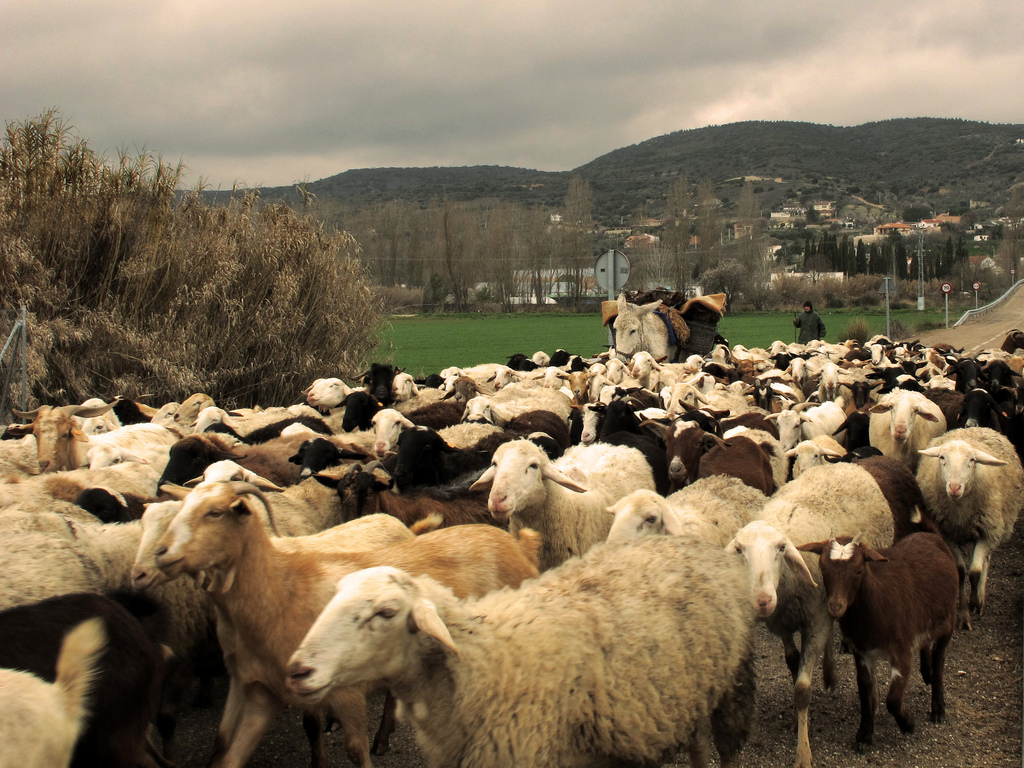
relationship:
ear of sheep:
[397, 610, 523, 712] [289, 552, 823, 758]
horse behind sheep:
[611, 284, 700, 364] [527, 335, 944, 560]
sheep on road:
[225, 513, 733, 758] [734, 664, 940, 760]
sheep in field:
[132, 474, 537, 704] [222, 286, 1018, 753]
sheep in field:
[460, 415, 675, 560] [242, 331, 1012, 710]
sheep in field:
[132, 420, 364, 513] [49, 374, 1022, 733]